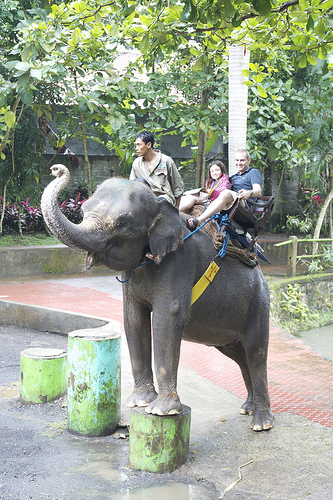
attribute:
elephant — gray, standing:
[53, 178, 283, 426]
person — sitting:
[202, 148, 230, 225]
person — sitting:
[231, 143, 259, 222]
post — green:
[23, 347, 65, 406]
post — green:
[128, 403, 188, 472]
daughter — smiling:
[206, 159, 231, 212]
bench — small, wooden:
[225, 199, 275, 244]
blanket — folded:
[200, 217, 264, 270]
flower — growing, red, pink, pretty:
[303, 185, 323, 209]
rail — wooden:
[278, 232, 332, 254]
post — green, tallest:
[67, 327, 125, 437]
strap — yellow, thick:
[186, 262, 228, 302]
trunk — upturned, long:
[45, 160, 87, 240]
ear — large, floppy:
[148, 190, 186, 259]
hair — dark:
[137, 130, 158, 146]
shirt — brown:
[135, 160, 182, 203]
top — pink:
[205, 180, 235, 196]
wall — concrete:
[4, 244, 86, 273]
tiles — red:
[272, 321, 330, 430]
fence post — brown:
[285, 231, 304, 274]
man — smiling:
[239, 147, 265, 209]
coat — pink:
[204, 174, 231, 205]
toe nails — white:
[150, 406, 180, 416]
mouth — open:
[75, 240, 103, 273]